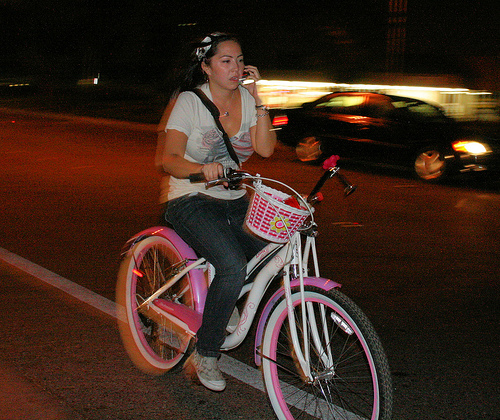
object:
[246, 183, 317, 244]
basket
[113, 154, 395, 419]
bike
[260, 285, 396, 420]
tire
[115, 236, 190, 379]
tire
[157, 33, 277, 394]
woman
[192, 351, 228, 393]
shoe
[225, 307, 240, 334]
shoe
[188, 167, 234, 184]
handle bar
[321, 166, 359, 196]
handle bar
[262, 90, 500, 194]
car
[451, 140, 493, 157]
headlight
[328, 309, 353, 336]
reflector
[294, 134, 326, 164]
tire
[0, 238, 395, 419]
line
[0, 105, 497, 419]
street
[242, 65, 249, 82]
cell phone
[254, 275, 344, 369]
fender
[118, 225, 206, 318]
fender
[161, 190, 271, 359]
jeans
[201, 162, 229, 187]
hand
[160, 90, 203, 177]
arm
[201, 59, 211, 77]
ear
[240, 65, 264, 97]
hand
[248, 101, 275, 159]
arm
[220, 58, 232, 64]
eye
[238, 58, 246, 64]
eye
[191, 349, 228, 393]
foot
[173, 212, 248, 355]
leg